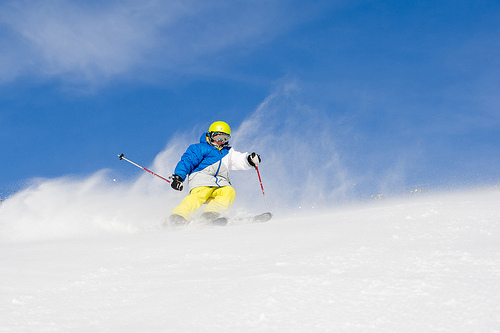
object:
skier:
[116, 120, 273, 224]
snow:
[0, 94, 497, 330]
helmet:
[207, 121, 230, 137]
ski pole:
[118, 152, 186, 192]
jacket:
[170, 133, 251, 189]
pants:
[170, 186, 236, 217]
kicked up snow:
[1, 164, 160, 230]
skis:
[160, 217, 230, 228]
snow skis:
[200, 211, 270, 227]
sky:
[0, 0, 500, 78]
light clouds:
[0, 1, 313, 103]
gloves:
[248, 150, 262, 166]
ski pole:
[249, 152, 270, 216]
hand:
[247, 153, 263, 168]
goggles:
[209, 134, 231, 144]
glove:
[170, 177, 184, 191]